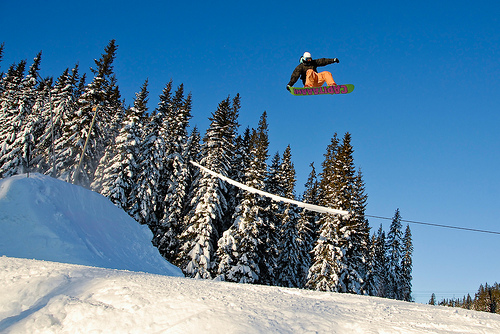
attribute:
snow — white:
[5, 168, 497, 333]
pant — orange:
[303, 67, 336, 85]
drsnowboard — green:
[288, 82, 355, 97]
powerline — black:
[220, 164, 499, 261]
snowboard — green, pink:
[283, 82, 359, 97]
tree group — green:
[426, 280, 499, 312]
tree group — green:
[1, 38, 414, 300]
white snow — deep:
[1, 174, 498, 332]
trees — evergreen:
[4, 38, 414, 305]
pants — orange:
[301, 68, 336, 85]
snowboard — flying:
[287, 79, 354, 96]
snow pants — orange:
[301, 69, 339, 91]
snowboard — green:
[227, 46, 422, 136]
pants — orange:
[305, 68, 335, 86]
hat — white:
[301, 53, 308, 60]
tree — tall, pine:
[309, 130, 368, 292]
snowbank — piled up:
[1, 171, 186, 280]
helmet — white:
[303, 51, 310, 58]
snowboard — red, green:
[286, 82, 357, 94]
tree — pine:
[58, 63, 279, 230]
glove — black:
[328, 45, 348, 72]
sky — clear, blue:
[0, 1, 499, 308]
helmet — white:
[301, 50, 313, 58]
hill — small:
[1, 171, 188, 281]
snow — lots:
[69, 216, 416, 320]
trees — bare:
[428, 279, 496, 310]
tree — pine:
[5, 49, 416, 303]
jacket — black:
[281, 55, 335, 86]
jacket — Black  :
[285, 57, 343, 83]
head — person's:
[296, 50, 316, 68]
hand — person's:
[329, 53, 342, 67]